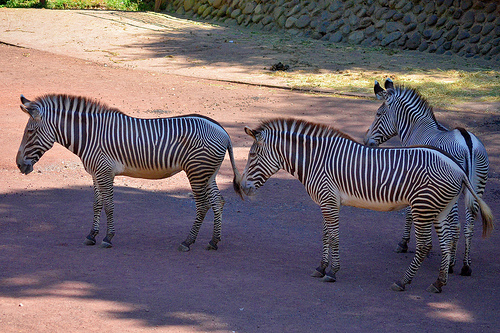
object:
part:
[68, 13, 285, 84]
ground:
[0, 10, 500, 333]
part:
[78, 258, 292, 319]